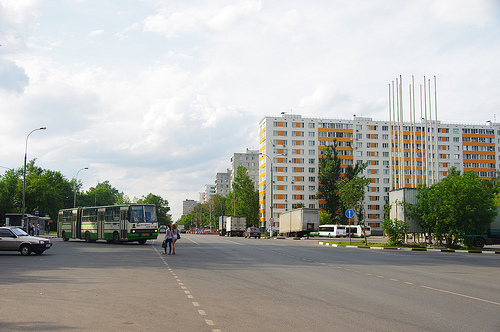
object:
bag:
[160, 238, 168, 250]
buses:
[310, 224, 346, 238]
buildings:
[253, 115, 500, 238]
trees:
[221, 167, 260, 231]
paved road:
[0, 231, 500, 332]